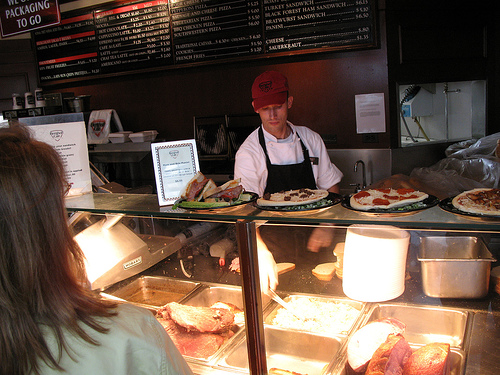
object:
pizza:
[270, 176, 371, 219]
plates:
[342, 216, 410, 309]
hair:
[5, 130, 67, 359]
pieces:
[348, 321, 473, 372]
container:
[323, 298, 478, 373]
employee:
[228, 66, 347, 266]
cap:
[251, 69, 288, 110]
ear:
[284, 95, 296, 108]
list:
[19, 118, 95, 201]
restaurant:
[5, 2, 492, 371]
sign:
[3, 2, 62, 40]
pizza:
[348, 180, 428, 210]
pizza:
[256, 183, 334, 204]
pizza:
[449, 183, 498, 223]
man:
[222, 68, 347, 193]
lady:
[0, 123, 185, 373]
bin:
[414, 226, 497, 302]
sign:
[144, 130, 209, 204]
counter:
[97, 185, 232, 232]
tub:
[415, 234, 496, 299]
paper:
[352, 90, 387, 137]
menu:
[0, 6, 384, 54]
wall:
[40, 27, 392, 106]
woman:
[2, 123, 193, 371]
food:
[183, 172, 312, 210]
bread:
[309, 254, 341, 280]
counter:
[265, 226, 396, 284]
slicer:
[69, 213, 176, 285]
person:
[244, 68, 338, 208]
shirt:
[232, 123, 344, 191]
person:
[232, 70, 339, 198]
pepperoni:
[357, 184, 416, 209]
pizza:
[351, 185, 377, 206]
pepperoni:
[381, 186, 404, 207]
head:
[236, 95, 303, 131]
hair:
[7, 176, 100, 333]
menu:
[116, 8, 200, 55]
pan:
[384, 306, 439, 329]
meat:
[362, 322, 424, 372]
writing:
[159, 143, 197, 193]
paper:
[149, 137, 206, 209]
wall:
[284, 4, 397, 141]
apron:
[259, 132, 315, 197]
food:
[409, 341, 448, 371]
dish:
[366, 329, 458, 373]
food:
[367, 329, 411, 373]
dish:
[163, 295, 234, 335]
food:
[164, 298, 234, 337]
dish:
[177, 173, 257, 209]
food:
[194, 172, 222, 202]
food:
[349, 180, 373, 207]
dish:
[255, 181, 332, 215]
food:
[261, 186, 317, 207]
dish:
[449, 177, 499, 221]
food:
[457, 182, 491, 216]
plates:
[172, 175, 494, 229]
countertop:
[13, 175, 494, 365]